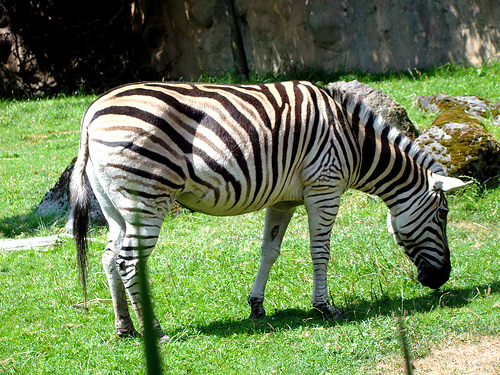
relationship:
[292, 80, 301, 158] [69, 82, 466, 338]
stripe on zebra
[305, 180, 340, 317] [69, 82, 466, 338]
leg on zebra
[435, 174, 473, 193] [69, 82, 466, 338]
ear on zebra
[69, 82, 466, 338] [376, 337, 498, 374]
zebra eating grass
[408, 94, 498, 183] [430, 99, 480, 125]
rock has moss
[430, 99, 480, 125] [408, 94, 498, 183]
moss on rock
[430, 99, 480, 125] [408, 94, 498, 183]
moss growing on rock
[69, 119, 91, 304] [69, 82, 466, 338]
tail on zebra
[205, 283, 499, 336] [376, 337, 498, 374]
shadow on grass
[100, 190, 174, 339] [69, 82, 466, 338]
back leg on zebra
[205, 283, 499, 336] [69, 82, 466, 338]
shadow of zebra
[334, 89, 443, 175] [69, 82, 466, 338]
mane on zebra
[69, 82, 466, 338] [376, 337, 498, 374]
zebra looking at grass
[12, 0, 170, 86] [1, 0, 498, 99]
shadow on wall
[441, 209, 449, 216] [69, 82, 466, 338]
eye on zebra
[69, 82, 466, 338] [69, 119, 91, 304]
zebra has tail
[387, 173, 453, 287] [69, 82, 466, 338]
head of zebra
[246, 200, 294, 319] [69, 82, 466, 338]
leg of zebra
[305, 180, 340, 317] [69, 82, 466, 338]
leg of zebra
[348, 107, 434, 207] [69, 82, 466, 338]
neck of zebra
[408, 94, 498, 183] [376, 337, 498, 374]
rock in grass